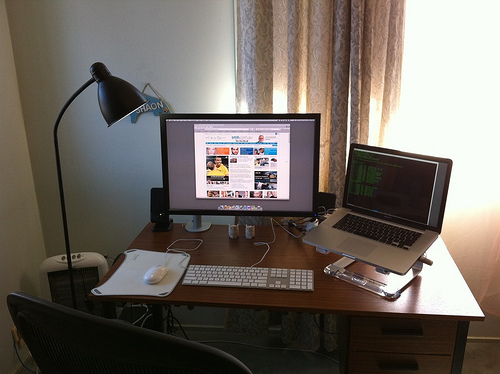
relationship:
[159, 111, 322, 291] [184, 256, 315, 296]
computer has keyboard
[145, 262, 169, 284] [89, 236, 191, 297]
mouse on mousepad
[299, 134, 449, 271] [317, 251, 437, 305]
laptop on stand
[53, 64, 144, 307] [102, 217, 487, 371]
lamp on desk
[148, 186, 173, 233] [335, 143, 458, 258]
speaker for computer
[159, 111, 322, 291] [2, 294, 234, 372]
computer has chair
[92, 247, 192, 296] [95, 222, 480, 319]
mouse pad on desk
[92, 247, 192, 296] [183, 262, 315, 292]
mouse pad next to keyboard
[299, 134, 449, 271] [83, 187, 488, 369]
laptop sitting on desk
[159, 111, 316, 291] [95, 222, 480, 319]
computer on desk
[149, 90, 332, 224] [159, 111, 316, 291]
monitor belonging to computer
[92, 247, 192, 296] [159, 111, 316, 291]
mouse pad lying next to computer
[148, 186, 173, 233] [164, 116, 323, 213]
speaker sitting next to monitor